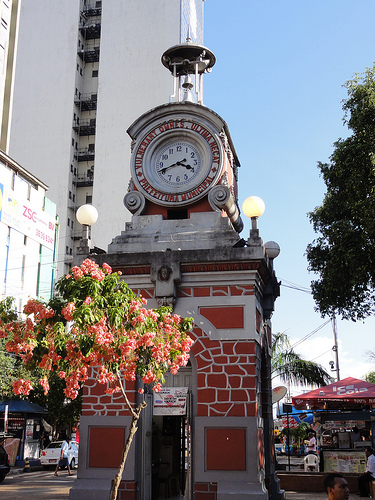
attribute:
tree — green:
[303, 57, 373, 323]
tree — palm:
[270, 327, 337, 389]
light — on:
[241, 195, 265, 218]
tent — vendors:
[289, 370, 372, 416]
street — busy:
[2, 428, 373, 494]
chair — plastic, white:
[299, 450, 319, 469]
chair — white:
[303, 450, 321, 474]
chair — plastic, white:
[303, 453, 320, 471]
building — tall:
[1, 0, 200, 305]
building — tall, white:
[13, 3, 213, 266]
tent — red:
[286, 371, 373, 482]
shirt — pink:
[304, 437, 320, 450]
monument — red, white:
[81, 22, 279, 376]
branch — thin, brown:
[18, 241, 200, 429]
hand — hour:
[175, 159, 194, 173]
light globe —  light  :
[240, 195, 266, 219]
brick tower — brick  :
[67, 32, 286, 498]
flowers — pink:
[73, 267, 83, 281]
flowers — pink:
[61, 300, 76, 318]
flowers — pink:
[134, 330, 155, 346]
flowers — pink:
[38, 374, 49, 395]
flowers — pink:
[85, 323, 98, 335]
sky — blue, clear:
[202, 1, 373, 410]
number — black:
[183, 145, 188, 154]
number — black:
[186, 150, 196, 158]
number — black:
[191, 158, 199, 166]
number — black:
[188, 166, 196, 173]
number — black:
[170, 171, 181, 183]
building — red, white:
[137, 261, 255, 493]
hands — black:
[161, 160, 195, 171]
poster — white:
[152, 386, 188, 416]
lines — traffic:
[13, 476, 72, 490]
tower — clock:
[68, 22, 276, 497]